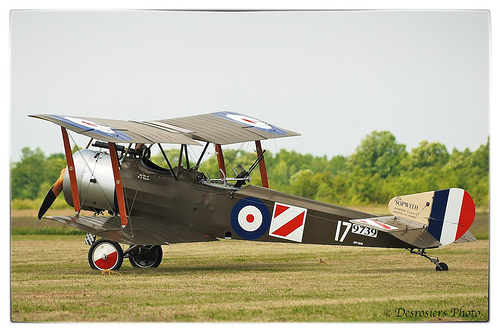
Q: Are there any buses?
A: No, there are no buses.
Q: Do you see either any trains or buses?
A: No, there are no buses or trains.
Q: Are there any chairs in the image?
A: No, there are no chairs.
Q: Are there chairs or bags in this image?
A: No, there are no chairs or bags.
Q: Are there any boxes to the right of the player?
A: Yes, there is a box to the right of the player.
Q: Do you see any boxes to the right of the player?
A: Yes, there is a box to the right of the player.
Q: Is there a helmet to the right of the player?
A: No, there is a box to the right of the player.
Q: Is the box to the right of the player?
A: Yes, the box is to the right of the player.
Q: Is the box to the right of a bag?
A: No, the box is to the right of the player.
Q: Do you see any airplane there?
A: Yes, there is an airplane.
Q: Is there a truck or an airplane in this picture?
A: Yes, there is an airplane.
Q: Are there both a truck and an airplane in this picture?
A: No, there is an airplane but no trucks.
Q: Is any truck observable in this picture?
A: No, there are no trucks.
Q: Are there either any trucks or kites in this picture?
A: No, there are no trucks or kites.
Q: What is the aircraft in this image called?
A: The aircraft is an airplane.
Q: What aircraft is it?
A: The aircraft is an airplane.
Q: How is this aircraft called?
A: This is an airplane.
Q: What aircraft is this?
A: This is an airplane.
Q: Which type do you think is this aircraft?
A: This is an airplane.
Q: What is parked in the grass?
A: The plane is parked in the grass.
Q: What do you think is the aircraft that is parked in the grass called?
A: The aircraft is an airplane.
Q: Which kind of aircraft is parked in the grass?
A: The aircraft is an airplane.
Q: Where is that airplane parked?
A: The airplane is parked in the grass.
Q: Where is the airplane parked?
A: The airplane is parked in the grass.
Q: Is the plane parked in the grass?
A: Yes, the plane is parked in the grass.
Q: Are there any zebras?
A: No, there are no zebras.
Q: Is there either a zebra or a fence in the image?
A: No, there are no zebras or fences.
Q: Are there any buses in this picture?
A: No, there are no buses.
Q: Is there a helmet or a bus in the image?
A: No, there are no buses or helmets.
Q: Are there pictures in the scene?
A: No, there are no pictures.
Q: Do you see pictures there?
A: No, there are no pictures.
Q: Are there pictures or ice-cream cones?
A: No, there are no pictures or ice-cream cones.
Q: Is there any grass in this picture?
A: Yes, there is grass.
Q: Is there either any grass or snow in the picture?
A: Yes, there is grass.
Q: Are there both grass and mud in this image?
A: No, there is grass but no mud.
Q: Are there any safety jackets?
A: No, there are no safety jackets.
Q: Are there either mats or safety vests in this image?
A: No, there are no safety vests or mats.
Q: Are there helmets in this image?
A: No, there are no helmets.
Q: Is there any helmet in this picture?
A: No, there are no helmets.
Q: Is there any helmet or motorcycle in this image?
A: No, there are no helmets or motorcycles.